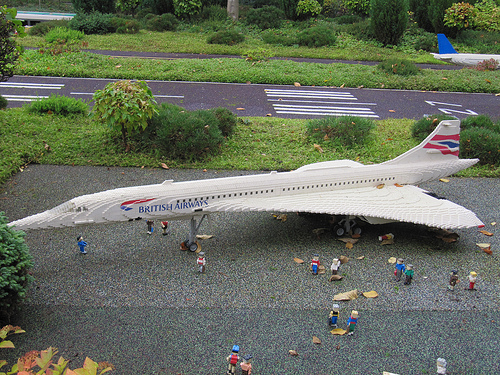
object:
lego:
[305, 283, 383, 345]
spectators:
[394, 258, 415, 286]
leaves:
[90, 79, 158, 132]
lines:
[272, 104, 376, 115]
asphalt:
[206, 85, 241, 106]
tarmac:
[0, 164, 500, 375]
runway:
[0, 76, 500, 126]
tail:
[382, 120, 460, 166]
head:
[406, 263, 414, 271]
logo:
[121, 197, 156, 212]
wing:
[193, 185, 483, 232]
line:
[66, 83, 181, 102]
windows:
[399, 164, 496, 205]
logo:
[422, 133, 460, 157]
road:
[0, 64, 498, 135]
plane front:
[3, 185, 144, 236]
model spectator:
[347, 310, 358, 336]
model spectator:
[329, 304, 340, 327]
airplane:
[3, 119, 485, 231]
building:
[6, 7, 78, 28]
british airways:
[138, 199, 209, 214]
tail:
[428, 27, 500, 73]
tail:
[437, 33, 459, 55]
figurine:
[77, 236, 88, 254]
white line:
[69, 90, 99, 100]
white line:
[149, 92, 187, 101]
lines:
[264, 84, 377, 119]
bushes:
[94, 79, 238, 159]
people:
[69, 235, 499, 373]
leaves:
[0, 323, 120, 375]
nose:
[0, 207, 55, 234]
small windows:
[177, 176, 398, 204]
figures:
[249, 244, 484, 341]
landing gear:
[183, 211, 207, 251]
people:
[300, 241, 423, 340]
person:
[403, 263, 415, 284]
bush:
[90, 79, 155, 149]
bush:
[148, 94, 182, 135]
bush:
[157, 106, 223, 162]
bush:
[208, 105, 238, 133]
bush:
[25, 91, 88, 113]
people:
[447, 270, 460, 291]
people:
[466, 271, 477, 291]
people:
[329, 257, 341, 276]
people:
[310, 253, 321, 275]